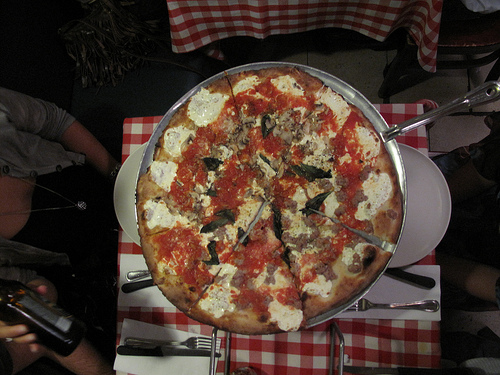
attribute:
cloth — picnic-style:
[369, 329, 461, 371]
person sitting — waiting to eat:
[30, 104, 104, 294]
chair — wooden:
[372, 1, 498, 96]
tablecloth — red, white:
[145, 13, 449, 80]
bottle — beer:
[5, 281, 91, 371]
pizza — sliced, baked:
[129, 52, 423, 339]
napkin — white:
[338, 263, 444, 318]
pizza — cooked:
[190, 135, 401, 285]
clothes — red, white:
[350, 317, 480, 374]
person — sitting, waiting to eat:
[2, 87, 115, 276]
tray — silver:
[134, 60, 406, 329]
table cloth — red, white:
[85, 77, 482, 374]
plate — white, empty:
[388, 130, 462, 270]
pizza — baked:
[205, 118, 341, 268]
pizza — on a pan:
[116, 43, 411, 339]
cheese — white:
[291, 187, 301, 204]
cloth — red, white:
[249, 336, 429, 374]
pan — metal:
[137, 60, 404, 335]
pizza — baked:
[128, 80, 413, 336]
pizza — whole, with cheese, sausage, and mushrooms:
[133, 80, 390, 341]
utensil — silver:
[112, 324, 224, 350]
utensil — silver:
[112, 340, 222, 365]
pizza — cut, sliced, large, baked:
[136, 67, 403, 335]